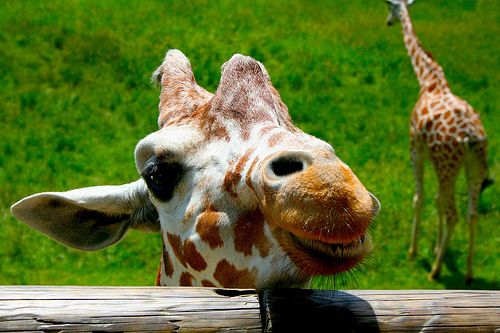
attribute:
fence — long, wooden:
[29, 277, 478, 326]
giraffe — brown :
[95, 27, 404, 302]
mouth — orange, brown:
[277, 188, 387, 276]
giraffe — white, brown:
[386, 2, 478, 279]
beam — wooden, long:
[88, 253, 458, 329]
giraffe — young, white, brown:
[7, 46, 384, 291]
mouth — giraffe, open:
[253, 161, 387, 273]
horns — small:
[153, 47, 292, 131]